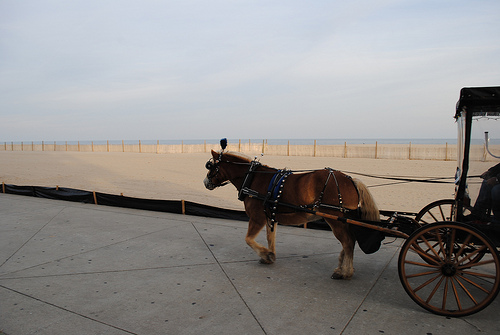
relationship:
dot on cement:
[208, 239, 220, 251] [2, 192, 498, 334]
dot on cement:
[254, 289, 264, 296] [2, 192, 498, 334]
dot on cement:
[230, 305, 250, 324] [39, 199, 323, 334]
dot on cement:
[86, 255, 99, 265] [18, 174, 384, 332]